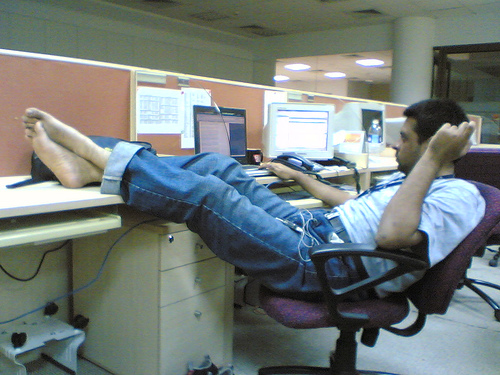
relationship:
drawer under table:
[160, 228, 221, 269] [1, 148, 398, 217]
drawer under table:
[160, 255, 224, 304] [1, 148, 398, 217]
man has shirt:
[21, 98, 486, 299] [332, 169, 484, 297]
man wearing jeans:
[21, 98, 486, 299] [100, 141, 369, 297]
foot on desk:
[22, 107, 113, 186] [1, 148, 398, 217]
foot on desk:
[22, 107, 99, 163] [1, 148, 398, 217]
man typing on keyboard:
[21, 98, 486, 299] [240, 164, 272, 175]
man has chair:
[21, 98, 486, 299] [257, 181, 497, 373]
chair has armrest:
[257, 181, 497, 373] [308, 243, 424, 325]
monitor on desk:
[192, 104, 247, 161] [1, 148, 398, 217]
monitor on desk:
[264, 102, 333, 163] [1, 148, 398, 217]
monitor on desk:
[335, 101, 387, 155] [1, 148, 398, 217]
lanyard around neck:
[354, 173, 455, 200] [434, 162, 454, 180]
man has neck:
[21, 98, 486, 299] [434, 162, 454, 180]